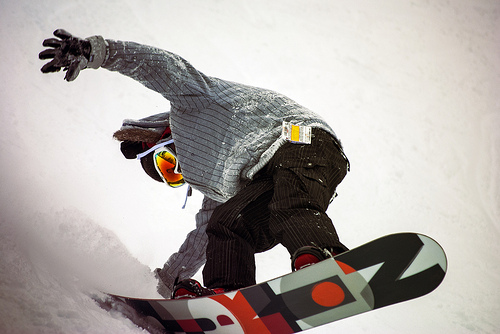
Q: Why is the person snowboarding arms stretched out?
A: For balance.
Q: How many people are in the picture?
A: One.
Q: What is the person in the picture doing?
A: Snowboarding.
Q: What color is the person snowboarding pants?
A: Black.